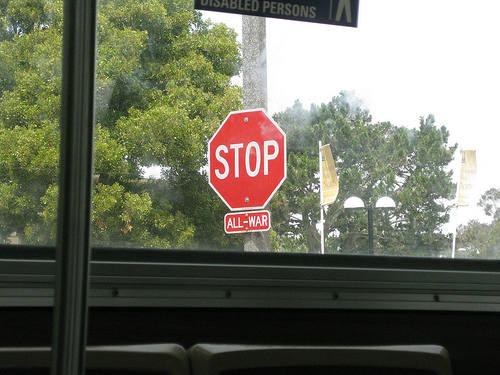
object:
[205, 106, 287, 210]
stop sign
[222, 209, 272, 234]
sign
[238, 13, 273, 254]
pole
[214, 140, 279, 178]
stop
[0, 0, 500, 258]
trees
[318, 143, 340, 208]
flag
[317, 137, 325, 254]
pole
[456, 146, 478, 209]
flag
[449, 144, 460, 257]
pole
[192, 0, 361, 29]
sign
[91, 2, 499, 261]
window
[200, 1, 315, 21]
text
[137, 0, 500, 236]
sky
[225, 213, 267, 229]
all war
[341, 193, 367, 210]
street lamp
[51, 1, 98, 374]
rail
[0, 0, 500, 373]
vehicle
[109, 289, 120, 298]
screw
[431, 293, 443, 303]
screw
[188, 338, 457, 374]
chair backs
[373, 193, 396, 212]
globe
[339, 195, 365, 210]
globe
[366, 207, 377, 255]
post